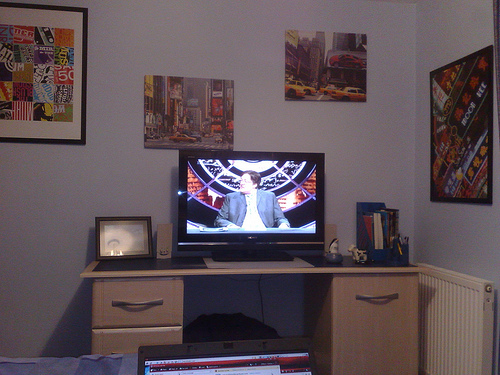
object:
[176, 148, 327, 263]
television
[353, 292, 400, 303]
handle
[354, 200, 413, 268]
rack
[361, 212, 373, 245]
book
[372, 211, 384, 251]
book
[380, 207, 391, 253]
book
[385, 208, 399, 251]
book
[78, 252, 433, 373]
desk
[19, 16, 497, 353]
room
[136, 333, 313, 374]
laptop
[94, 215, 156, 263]
certificate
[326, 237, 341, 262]
figurine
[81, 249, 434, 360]
bird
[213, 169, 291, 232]
person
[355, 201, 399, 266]
holder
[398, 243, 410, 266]
holder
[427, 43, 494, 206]
artwork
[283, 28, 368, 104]
artwork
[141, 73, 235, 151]
artwork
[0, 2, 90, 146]
artwork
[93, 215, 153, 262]
photo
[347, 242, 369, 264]
cow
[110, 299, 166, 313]
handle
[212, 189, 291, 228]
jacket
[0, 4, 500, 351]
wall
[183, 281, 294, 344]
dark objects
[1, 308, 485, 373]
foreground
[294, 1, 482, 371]
corner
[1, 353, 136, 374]
pillow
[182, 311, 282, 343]
object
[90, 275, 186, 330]
drawer